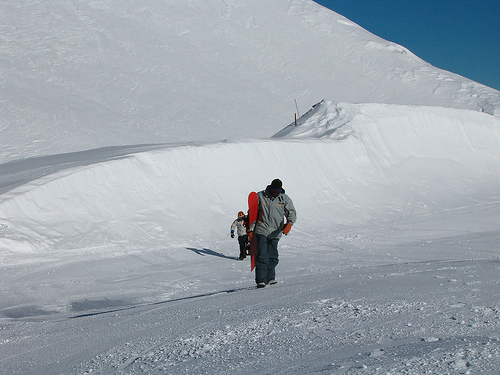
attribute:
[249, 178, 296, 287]
man — snowboarder, snowboarding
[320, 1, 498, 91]
blues sky — blue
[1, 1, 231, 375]
white snow — fresh powder snow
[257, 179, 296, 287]
snowboarder — walking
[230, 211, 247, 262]
man — walking, snowboarder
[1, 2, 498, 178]
snow — white fluffy snow